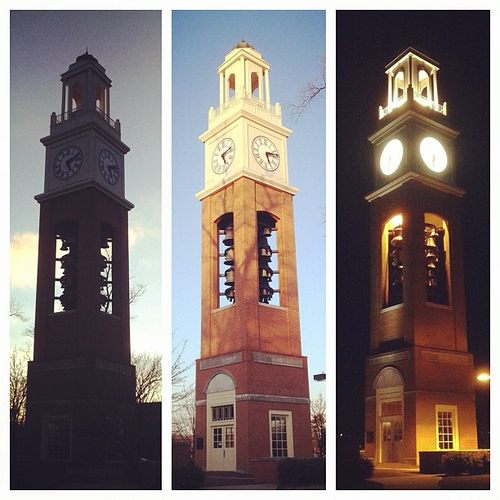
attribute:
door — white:
[195, 404, 233, 468]